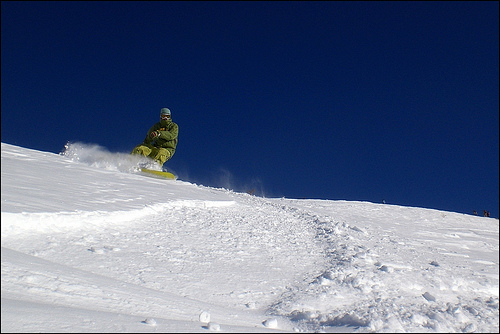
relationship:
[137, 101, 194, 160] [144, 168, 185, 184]
man on board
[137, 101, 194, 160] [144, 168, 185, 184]
man in board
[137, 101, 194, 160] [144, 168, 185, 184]
man using board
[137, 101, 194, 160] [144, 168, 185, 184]
man with board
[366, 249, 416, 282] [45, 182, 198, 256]
snow on ground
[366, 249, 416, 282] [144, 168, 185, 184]
snow on board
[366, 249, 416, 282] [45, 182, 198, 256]
snow in ground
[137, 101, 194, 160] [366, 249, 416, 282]
man in snow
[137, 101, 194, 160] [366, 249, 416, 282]
man on snow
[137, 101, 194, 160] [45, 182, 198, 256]
man in ground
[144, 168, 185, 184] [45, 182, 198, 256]
board on ground